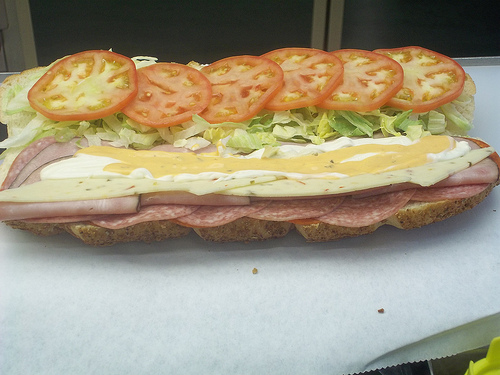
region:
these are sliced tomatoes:
[30, 54, 464, 114]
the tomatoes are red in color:
[188, 60, 431, 105]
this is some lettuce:
[233, 117, 450, 131]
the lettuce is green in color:
[291, 113, 453, 130]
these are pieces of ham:
[114, 190, 448, 217]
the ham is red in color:
[213, 209, 385, 219]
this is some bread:
[97, 222, 332, 237]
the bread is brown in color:
[204, 228, 312, 245]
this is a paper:
[183, 257, 361, 351]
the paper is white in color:
[213, 257, 309, 350]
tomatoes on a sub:
[58, 43, 437, 128]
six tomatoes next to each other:
[51, 24, 460, 134]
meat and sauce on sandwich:
[38, 130, 473, 263]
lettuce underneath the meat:
[136, 108, 431, 150]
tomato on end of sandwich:
[45, 43, 125, 130]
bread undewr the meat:
[386, 199, 470, 251]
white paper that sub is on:
[101, 243, 317, 345]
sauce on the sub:
[82, 132, 441, 199]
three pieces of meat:
[136, 197, 313, 249]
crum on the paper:
[337, 270, 412, 353]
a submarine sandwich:
[17, 34, 497, 281]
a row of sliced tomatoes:
[37, 51, 462, 97]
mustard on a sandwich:
[100, 145, 436, 171]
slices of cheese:
[32, 176, 448, 192]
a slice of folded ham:
[16, 198, 136, 219]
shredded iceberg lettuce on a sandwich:
[78, 111, 448, 146]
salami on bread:
[75, 201, 472, 242]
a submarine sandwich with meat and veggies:
[30, 40, 481, 230]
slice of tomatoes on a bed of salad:
[10, 38, 496, 143]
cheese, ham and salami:
[33, 170, 489, 219]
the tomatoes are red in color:
[183, 65, 271, 110]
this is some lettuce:
[266, 113, 410, 135]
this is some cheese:
[53, 150, 455, 187]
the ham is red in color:
[276, 195, 395, 216]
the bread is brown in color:
[133, 225, 313, 238]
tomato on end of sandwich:
[396, 33, 469, 110]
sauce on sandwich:
[244, 141, 371, 181]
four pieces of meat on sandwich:
[144, 191, 406, 236]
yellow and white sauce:
[208, 147, 290, 194]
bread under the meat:
[421, 190, 456, 224]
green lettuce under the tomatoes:
[261, 112, 318, 144]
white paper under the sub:
[243, 277, 319, 338]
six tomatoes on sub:
[49, 40, 444, 135]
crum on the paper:
[206, 255, 305, 306]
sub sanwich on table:
[21, 28, 493, 254]